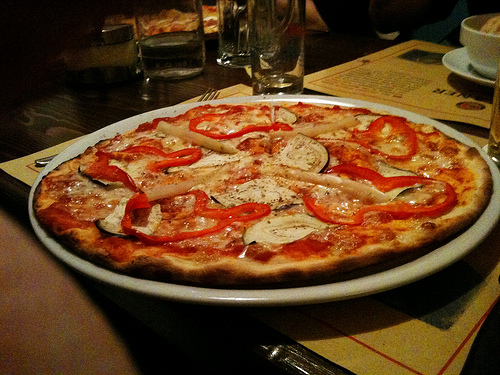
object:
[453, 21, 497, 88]
bowl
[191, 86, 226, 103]
fork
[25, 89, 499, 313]
plate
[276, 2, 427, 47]
person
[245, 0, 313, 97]
glass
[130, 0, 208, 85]
glass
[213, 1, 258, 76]
glass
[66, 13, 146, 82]
glass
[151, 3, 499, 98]
table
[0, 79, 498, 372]
place mat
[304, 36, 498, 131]
place mat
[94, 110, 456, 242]
peppers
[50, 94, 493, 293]
pizza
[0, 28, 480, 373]
table